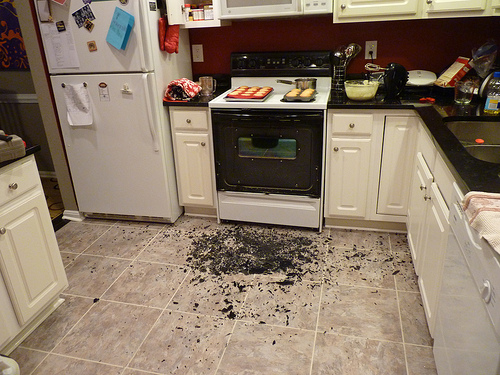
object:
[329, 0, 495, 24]
cabinets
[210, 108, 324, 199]
oven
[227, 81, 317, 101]
food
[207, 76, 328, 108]
stove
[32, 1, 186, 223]
fridge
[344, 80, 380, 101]
bowl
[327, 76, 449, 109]
counter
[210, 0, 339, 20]
microwave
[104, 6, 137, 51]
paper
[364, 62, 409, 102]
mixer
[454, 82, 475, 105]
cup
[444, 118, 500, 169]
sink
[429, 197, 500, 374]
dishwasher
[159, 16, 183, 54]
mitts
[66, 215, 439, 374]
stuff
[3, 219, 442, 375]
floor